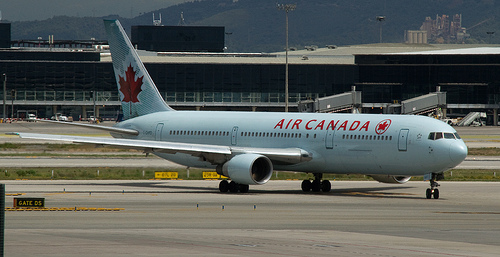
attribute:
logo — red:
[270, 110, 401, 144]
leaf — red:
[114, 62, 153, 107]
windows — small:
[427, 127, 467, 150]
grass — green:
[59, 157, 209, 181]